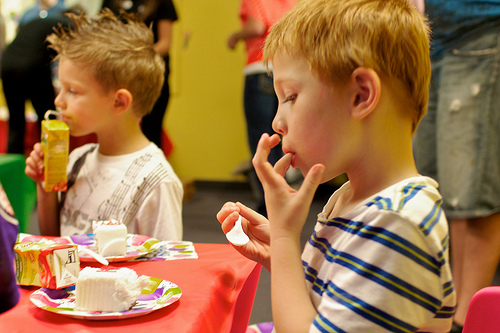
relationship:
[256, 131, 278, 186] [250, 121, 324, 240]
finger on hand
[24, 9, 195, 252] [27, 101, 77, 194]
boy with juice box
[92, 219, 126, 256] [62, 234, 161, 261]
cake on plate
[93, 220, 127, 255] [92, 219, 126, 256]
frosting on cake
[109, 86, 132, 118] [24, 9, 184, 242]
ear on boy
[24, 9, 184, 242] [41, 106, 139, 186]
boy with box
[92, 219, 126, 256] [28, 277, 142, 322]
cake is on plate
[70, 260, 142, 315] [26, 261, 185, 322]
cake is on plate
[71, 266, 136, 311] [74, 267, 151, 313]
white frosting is on cake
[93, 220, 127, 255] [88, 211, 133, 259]
frosting is on cake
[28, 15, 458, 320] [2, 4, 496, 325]
party in scene